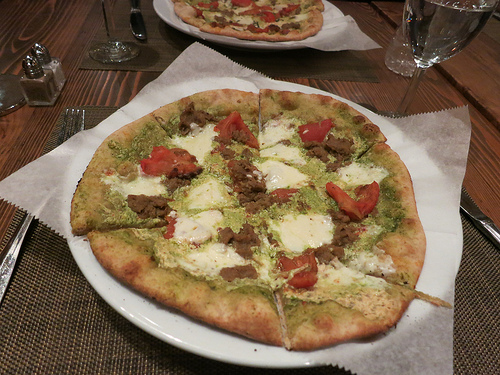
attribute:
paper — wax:
[5, 152, 71, 244]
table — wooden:
[45, 0, 482, 332]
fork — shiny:
[4, 86, 105, 293]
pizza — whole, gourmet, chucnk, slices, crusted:
[104, 104, 407, 299]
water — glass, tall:
[388, 8, 485, 118]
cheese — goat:
[177, 111, 207, 151]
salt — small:
[14, 40, 64, 93]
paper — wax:
[138, 62, 202, 106]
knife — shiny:
[407, 124, 499, 277]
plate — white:
[71, 107, 460, 363]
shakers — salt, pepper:
[12, 33, 99, 102]